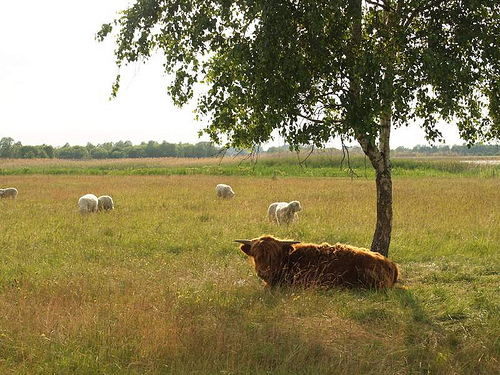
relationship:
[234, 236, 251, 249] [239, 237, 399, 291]
horn of bull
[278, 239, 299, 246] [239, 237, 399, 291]
horn of bull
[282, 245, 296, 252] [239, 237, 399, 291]
ear of bull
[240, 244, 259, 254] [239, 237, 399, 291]
ear of bull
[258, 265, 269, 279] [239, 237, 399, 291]
nose of bull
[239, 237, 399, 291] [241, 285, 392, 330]
bull in grass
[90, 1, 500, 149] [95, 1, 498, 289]
leaves on tree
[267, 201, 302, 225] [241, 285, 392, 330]
sheep in grass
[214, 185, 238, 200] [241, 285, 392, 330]
sheep in grass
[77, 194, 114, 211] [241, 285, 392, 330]
sheep in grass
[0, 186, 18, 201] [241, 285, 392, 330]
sheep in grass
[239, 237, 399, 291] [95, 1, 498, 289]
bull under tree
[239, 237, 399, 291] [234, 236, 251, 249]
bull has horn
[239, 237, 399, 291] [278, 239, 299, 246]
bull has horn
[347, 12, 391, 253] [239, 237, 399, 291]
trunk behind bull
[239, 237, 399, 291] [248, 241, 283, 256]
bull has fur